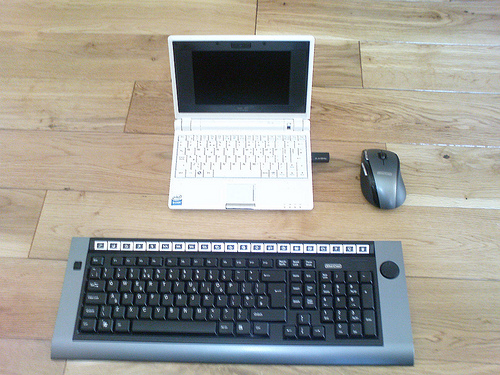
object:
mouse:
[357, 146, 410, 211]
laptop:
[161, 32, 317, 214]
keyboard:
[48, 234, 416, 367]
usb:
[311, 151, 331, 164]